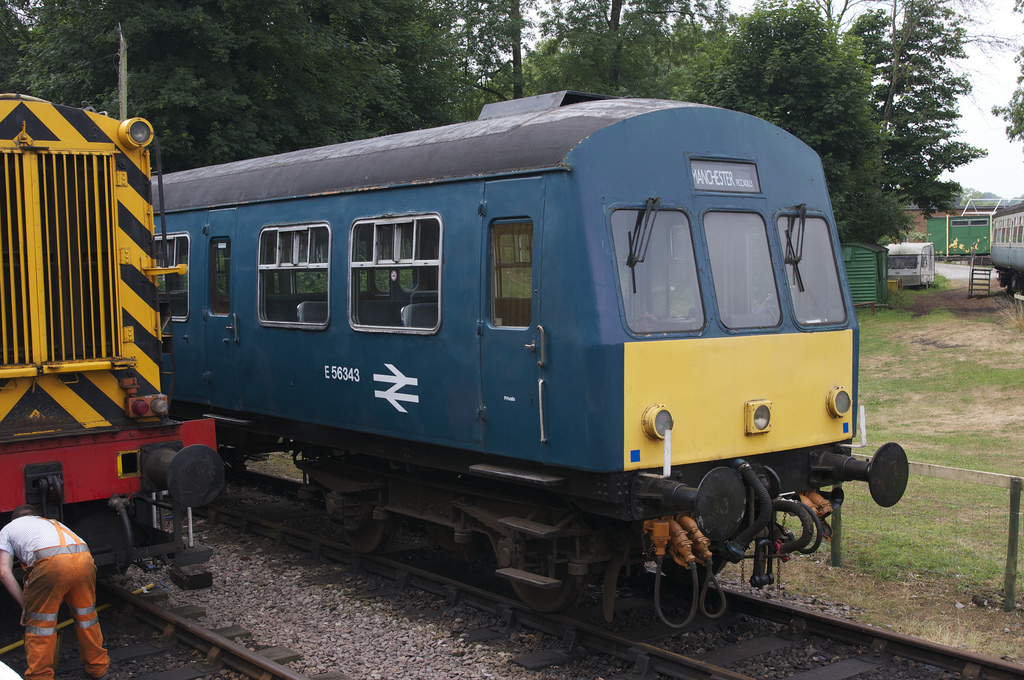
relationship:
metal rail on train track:
[165, 484, 821, 668] [9, 435, 1018, 669]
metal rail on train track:
[729, 571, 1018, 669] [9, 435, 1018, 669]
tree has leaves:
[717, 5, 920, 268] [717, 5, 877, 215]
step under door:
[491, 555, 572, 595] [476, 185, 550, 465]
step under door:
[467, 495, 565, 543] [476, 185, 550, 465]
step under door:
[462, 462, 562, 495] [476, 185, 550, 465]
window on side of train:
[158, 218, 190, 327] [129, 88, 913, 621]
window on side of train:
[256, 218, 330, 327] [129, 88, 913, 621]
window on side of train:
[345, 218, 443, 330] [129, 88, 913, 621]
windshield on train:
[609, 205, 853, 336] [129, 88, 913, 621]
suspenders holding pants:
[31, 506, 86, 545] [28, 546, 106, 677]